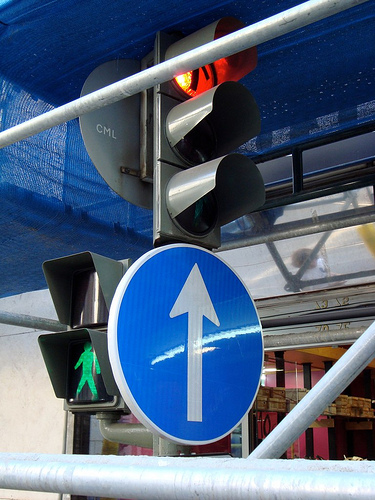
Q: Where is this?
A: This is at the street.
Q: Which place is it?
A: It is a street.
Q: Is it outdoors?
A: Yes, it is outdoors.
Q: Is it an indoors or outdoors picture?
A: It is outdoors.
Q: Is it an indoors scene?
A: No, it is outdoors.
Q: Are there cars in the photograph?
A: No, there are no cars.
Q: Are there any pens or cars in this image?
A: No, there are no cars or pens.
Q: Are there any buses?
A: No, there are no buses.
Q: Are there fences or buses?
A: No, there are no buses or fences.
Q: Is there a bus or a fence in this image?
A: No, there are no buses or fences.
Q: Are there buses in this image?
A: No, there are no buses.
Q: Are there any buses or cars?
A: No, there are no buses or cars.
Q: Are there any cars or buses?
A: No, there are no buses or cars.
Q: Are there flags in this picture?
A: No, there are no flags.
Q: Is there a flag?
A: No, there are no flags.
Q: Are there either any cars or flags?
A: No, there are no flags or cars.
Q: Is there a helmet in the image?
A: No, there are no helmets.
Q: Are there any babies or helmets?
A: No, there are no helmets or babies.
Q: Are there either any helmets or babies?
A: No, there are no helmets or babies.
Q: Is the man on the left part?
A: Yes, the man is on the left of the image.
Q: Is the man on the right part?
A: No, the man is on the left of the image.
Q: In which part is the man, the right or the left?
A: The man is on the left of the image.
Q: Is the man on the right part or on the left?
A: The man is on the left of the image.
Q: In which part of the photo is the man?
A: The man is on the left of the image.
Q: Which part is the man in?
A: The man is on the left of the image.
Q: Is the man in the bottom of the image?
A: Yes, the man is in the bottom of the image.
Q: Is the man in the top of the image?
A: No, the man is in the bottom of the image.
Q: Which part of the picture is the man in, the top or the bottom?
A: The man is in the bottom of the image.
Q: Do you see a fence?
A: No, there are no fences.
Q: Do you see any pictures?
A: No, there are no pictures.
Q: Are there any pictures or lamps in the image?
A: No, there are no pictures or lamps.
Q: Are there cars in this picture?
A: No, there are no cars.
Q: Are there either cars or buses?
A: No, there are no cars or buses.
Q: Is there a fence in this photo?
A: No, there are no fences.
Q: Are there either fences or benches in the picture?
A: No, there are no fences or benches.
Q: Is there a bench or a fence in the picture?
A: No, there are no fences or benches.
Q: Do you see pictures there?
A: No, there are no pictures.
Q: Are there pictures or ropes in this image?
A: No, there are no pictures or ropes.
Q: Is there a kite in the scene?
A: No, there are no kites.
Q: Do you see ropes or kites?
A: No, there are no kites or ropes.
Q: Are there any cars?
A: No, there are no cars.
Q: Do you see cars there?
A: No, there are no cars.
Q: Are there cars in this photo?
A: No, there are no cars.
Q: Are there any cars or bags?
A: No, there are no cars or bags.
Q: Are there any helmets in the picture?
A: No, there are no helmets.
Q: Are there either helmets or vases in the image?
A: No, there are no helmets or vases.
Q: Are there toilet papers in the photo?
A: No, there are no toilet papers.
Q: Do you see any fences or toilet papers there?
A: No, there are no toilet papers or fences.